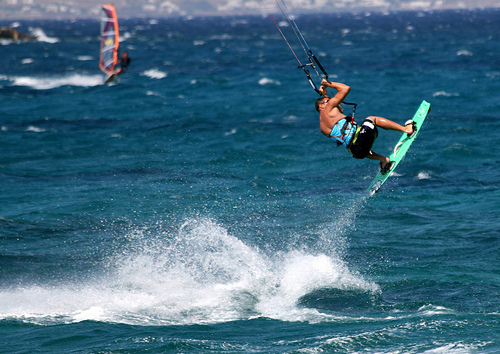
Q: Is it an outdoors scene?
A: Yes, it is outdoors.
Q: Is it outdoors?
A: Yes, it is outdoors.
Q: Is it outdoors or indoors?
A: It is outdoors.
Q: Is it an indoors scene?
A: No, it is outdoors.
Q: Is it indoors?
A: No, it is outdoors.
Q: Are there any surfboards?
A: Yes, there is a surfboard.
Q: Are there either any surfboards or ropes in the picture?
A: Yes, there is a surfboard.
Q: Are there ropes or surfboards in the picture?
A: Yes, there is a surfboard.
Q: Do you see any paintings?
A: No, there are no paintings.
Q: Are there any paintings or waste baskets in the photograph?
A: No, there are no paintings or waste baskets.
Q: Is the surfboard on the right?
A: Yes, the surfboard is on the right of the image.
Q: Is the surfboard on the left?
A: No, the surfboard is on the right of the image.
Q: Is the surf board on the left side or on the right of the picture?
A: The surf board is on the right of the image.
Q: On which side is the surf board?
A: The surf board is on the right of the image.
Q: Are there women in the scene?
A: No, there are no women.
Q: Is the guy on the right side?
A: Yes, the guy is on the right of the image.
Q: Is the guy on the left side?
A: No, the guy is on the right of the image.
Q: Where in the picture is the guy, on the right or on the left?
A: The guy is on the right of the image.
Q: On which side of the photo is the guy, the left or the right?
A: The guy is on the right of the image.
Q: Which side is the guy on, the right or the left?
A: The guy is on the right of the image.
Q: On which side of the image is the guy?
A: The guy is on the right of the image.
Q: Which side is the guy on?
A: The guy is on the right of the image.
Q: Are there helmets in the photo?
A: No, there are no helmets.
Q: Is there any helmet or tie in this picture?
A: No, there are no helmets or ties.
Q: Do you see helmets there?
A: No, there are no helmets.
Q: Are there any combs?
A: No, there are no combs.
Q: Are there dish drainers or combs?
A: No, there are no combs or dish drainers.